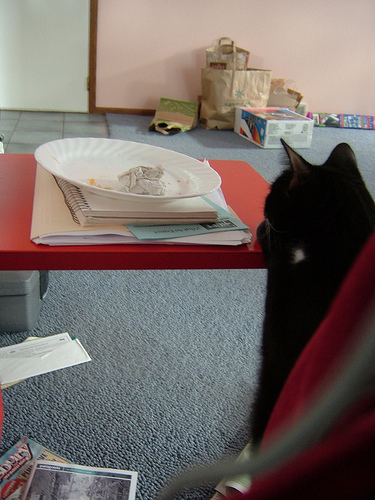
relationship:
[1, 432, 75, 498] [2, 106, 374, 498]
booklet lying on floor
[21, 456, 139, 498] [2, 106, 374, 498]
booklet lying on floor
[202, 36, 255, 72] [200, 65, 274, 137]
bag sitting inside bag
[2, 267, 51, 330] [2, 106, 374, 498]
safe sitting on floor